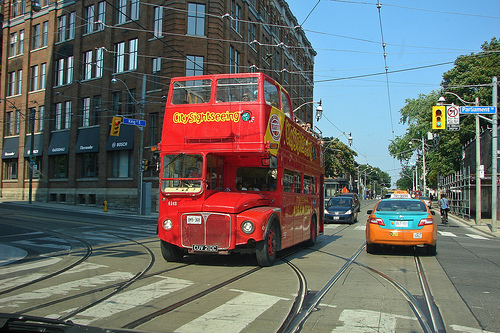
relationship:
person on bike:
[439, 193, 450, 226] [441, 209, 449, 226]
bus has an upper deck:
[158, 69, 326, 262] [165, 75, 326, 171]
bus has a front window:
[158, 69, 326, 262] [161, 153, 204, 194]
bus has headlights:
[158, 69, 326, 262] [242, 220, 254, 236]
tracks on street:
[415, 253, 447, 331] [2, 258, 451, 332]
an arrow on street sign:
[447, 105, 461, 119] [447, 106, 461, 128]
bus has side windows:
[158, 69, 326, 262] [282, 171, 315, 199]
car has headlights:
[324, 194, 357, 222] [346, 207, 352, 215]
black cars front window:
[324, 194, 357, 222] [329, 196, 352, 207]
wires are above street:
[376, 2, 398, 134] [2, 258, 451, 332]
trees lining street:
[411, 38, 499, 198] [2, 258, 451, 332]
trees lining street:
[321, 135, 392, 198] [2, 258, 451, 332]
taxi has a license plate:
[366, 198, 437, 252] [393, 220, 409, 228]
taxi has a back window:
[366, 198, 437, 252] [378, 198, 426, 212]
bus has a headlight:
[158, 69, 326, 262] [242, 220, 254, 236]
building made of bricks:
[1, 1, 159, 214] [164, 0, 187, 75]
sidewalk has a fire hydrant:
[1, 196, 158, 221] [102, 196, 109, 212]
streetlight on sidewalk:
[110, 70, 148, 220] [1, 196, 158, 221]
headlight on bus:
[164, 218, 173, 231] [158, 69, 326, 262]